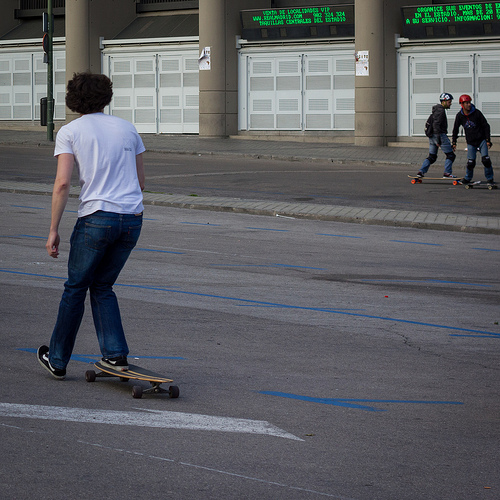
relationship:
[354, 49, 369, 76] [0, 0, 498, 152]
flyer on building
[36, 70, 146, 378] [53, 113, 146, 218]
guy wearing white shirt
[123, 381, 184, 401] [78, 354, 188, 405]
wheels on skateboard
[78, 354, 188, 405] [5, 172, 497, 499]
skateboard in street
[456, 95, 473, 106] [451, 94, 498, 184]
helmet on skateboarder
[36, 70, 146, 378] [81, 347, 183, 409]
guy on board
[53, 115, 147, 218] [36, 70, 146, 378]
white shirt on guy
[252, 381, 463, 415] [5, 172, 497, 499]
lines in street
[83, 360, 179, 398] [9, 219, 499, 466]
skateboard in street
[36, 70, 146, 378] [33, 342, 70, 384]
guy wearing shoe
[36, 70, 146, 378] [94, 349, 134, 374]
guy wearing shoe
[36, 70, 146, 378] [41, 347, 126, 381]
guy wearing shoes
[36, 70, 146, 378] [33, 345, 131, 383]
guy wearing shoes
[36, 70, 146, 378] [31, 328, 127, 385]
guy wearing shoes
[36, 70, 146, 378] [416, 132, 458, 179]
guy wearing jeans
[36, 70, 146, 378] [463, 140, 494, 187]
guy wearing jeans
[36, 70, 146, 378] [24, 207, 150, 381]
guy wearing jeans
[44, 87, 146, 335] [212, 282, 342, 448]
guy skateboarding in street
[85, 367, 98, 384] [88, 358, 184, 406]
wheel of skateboard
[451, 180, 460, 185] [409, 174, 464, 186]
wheel of skateboard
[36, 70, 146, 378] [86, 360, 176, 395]
guy riding skateboard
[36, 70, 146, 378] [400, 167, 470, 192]
guy riding skateboard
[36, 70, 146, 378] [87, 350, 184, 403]
guy on board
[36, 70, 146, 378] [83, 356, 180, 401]
guy on skateboard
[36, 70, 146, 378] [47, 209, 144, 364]
guy wearing jeans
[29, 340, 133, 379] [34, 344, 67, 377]
shoes made by shoes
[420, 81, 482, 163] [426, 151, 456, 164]
they wearing pads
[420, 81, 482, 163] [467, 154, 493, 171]
they wearing pads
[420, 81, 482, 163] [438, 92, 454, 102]
they wearing helmet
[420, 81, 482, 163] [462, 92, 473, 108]
they wearing helmet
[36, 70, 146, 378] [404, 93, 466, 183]
guy riding man/skateboard